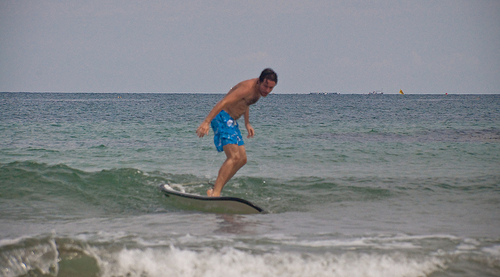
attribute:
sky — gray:
[108, 10, 451, 66]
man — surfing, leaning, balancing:
[194, 65, 288, 194]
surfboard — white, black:
[159, 177, 268, 218]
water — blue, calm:
[64, 94, 211, 110]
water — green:
[381, 148, 448, 176]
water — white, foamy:
[127, 249, 415, 276]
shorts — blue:
[209, 113, 251, 150]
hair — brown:
[260, 69, 281, 83]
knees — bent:
[225, 146, 259, 170]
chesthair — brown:
[244, 97, 258, 107]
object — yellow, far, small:
[392, 84, 410, 97]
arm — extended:
[192, 91, 238, 138]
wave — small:
[19, 157, 154, 209]